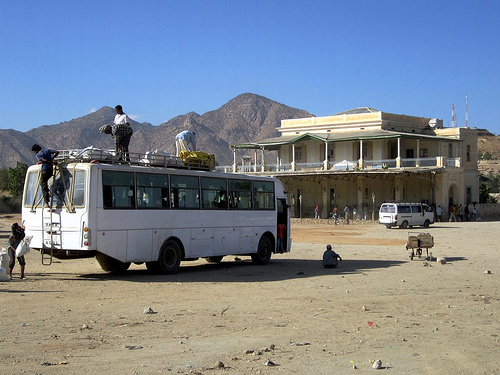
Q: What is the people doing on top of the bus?
A: Getting baggage.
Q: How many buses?
A: Two.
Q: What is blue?
A: Sky.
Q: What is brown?
A: Dirt.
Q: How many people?
A: Three.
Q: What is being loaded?
A: Supplies.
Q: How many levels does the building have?
A: Two.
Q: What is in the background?
A: Mountains.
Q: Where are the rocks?
A: In the dirt.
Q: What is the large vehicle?
A: Bus.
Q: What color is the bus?
A: White.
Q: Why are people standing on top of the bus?
A: Get luggage.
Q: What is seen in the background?
A: Mountains.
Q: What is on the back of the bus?
A: Ladder.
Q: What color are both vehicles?
A: White.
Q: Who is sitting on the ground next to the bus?
A: A child.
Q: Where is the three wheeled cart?
A: Right of child.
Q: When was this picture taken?
A: Daytime.